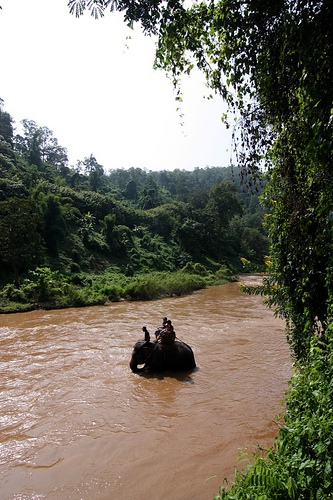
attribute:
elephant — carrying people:
[129, 333, 198, 401]